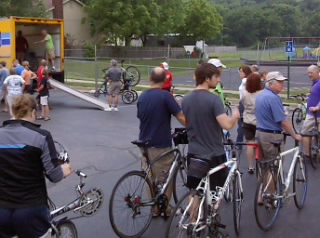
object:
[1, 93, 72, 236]
woman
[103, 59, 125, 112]
man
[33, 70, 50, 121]
girl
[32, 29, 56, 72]
man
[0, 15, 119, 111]
truck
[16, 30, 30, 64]
man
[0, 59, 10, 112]
man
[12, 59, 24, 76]
man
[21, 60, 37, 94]
girl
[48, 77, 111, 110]
truck ramp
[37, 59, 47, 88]
man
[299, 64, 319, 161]
man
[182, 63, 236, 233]
people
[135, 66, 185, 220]
man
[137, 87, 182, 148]
shirt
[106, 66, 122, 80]
shirt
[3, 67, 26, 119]
man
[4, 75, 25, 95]
shirt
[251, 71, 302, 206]
man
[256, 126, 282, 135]
belt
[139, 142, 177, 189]
shorts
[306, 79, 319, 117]
shirt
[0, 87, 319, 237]
parking lot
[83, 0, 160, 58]
tree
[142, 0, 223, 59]
tree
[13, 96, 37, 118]
hair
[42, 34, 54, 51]
shirt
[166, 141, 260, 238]
bicycle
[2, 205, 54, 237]
shorts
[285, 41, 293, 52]
sign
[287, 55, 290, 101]
pole